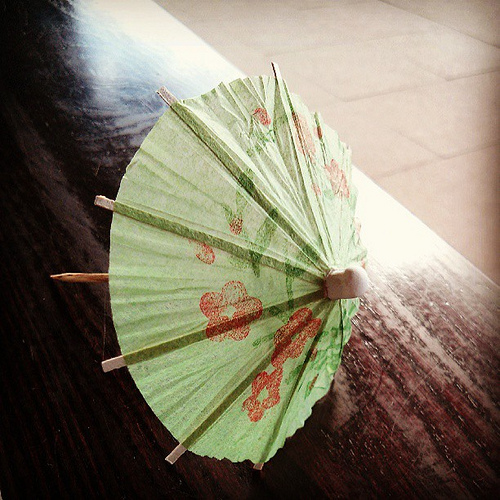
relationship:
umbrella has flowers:
[49, 60, 368, 470] [187, 107, 351, 421]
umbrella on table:
[49, 60, 368, 470] [0, 0, 499, 500]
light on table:
[61, 0, 469, 275] [0, 0, 499, 500]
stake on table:
[49, 271, 109, 283] [0, 0, 499, 500]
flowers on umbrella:
[187, 107, 351, 421] [49, 60, 368, 470]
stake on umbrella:
[49, 271, 109, 283] [49, 60, 368, 470]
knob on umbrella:
[327, 264, 368, 300] [49, 60, 368, 470]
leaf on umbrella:
[223, 171, 321, 303] [49, 60, 368, 470]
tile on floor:
[156, 0, 499, 284] [154, 0, 499, 293]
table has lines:
[0, 0, 499, 500] [0, 208, 499, 499]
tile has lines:
[156, 0, 499, 284] [223, 2, 499, 180]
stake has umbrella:
[49, 271, 109, 283] [49, 60, 368, 470]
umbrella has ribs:
[49, 60, 368, 470] [93, 61, 366, 473]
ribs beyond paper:
[93, 61, 366, 473] [108, 74, 368, 464]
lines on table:
[0, 208, 499, 499] [0, 0, 499, 500]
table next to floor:
[0, 0, 499, 500] [154, 0, 499, 293]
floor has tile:
[154, 0, 499, 293] [156, 0, 499, 284]